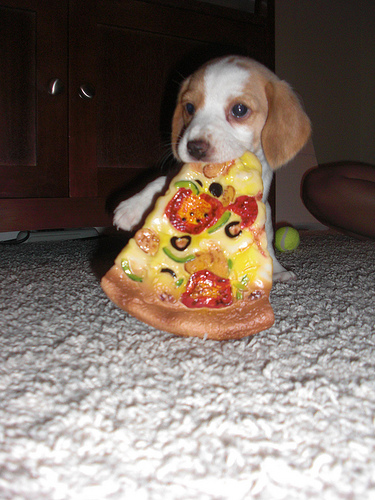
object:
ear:
[260, 77, 312, 170]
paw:
[112, 182, 145, 230]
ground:
[6, 307, 228, 488]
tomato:
[166, 187, 219, 237]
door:
[3, 2, 70, 198]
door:
[69, 5, 267, 191]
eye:
[230, 100, 253, 121]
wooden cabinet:
[0, 0, 275, 228]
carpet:
[1, 225, 372, 499]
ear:
[171, 76, 194, 161]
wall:
[272, 1, 371, 229]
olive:
[167, 230, 197, 255]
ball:
[273, 227, 301, 254]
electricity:
[10, 217, 110, 250]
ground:
[5, 242, 111, 298]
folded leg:
[299, 161, 375, 240]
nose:
[187, 142, 209, 155]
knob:
[75, 81, 95, 100]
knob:
[49, 75, 63, 99]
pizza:
[99, 148, 275, 340]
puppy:
[111, 56, 313, 285]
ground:
[43, 360, 163, 483]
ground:
[227, 341, 333, 448]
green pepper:
[171, 177, 199, 194]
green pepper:
[159, 243, 197, 264]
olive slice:
[223, 218, 241, 239]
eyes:
[184, 102, 197, 118]